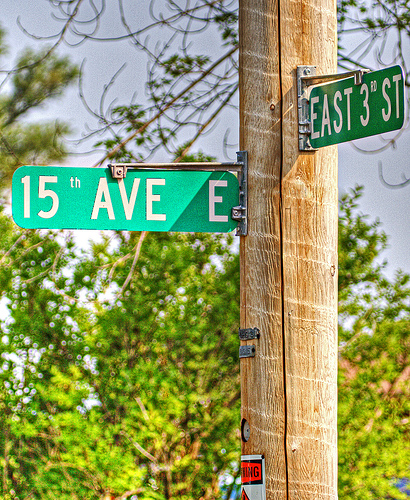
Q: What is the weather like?
A: It is clear.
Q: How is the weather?
A: It is clear.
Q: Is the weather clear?
A: Yes, it is clear.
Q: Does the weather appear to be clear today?
A: Yes, it is clear.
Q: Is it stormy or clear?
A: It is clear.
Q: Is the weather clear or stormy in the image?
A: It is clear.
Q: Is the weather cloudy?
A: No, it is clear.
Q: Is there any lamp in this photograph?
A: No, there are no lamps.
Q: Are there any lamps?
A: No, there are no lamps.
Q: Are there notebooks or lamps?
A: No, there are no lamps or notebooks.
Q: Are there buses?
A: No, there are no buses.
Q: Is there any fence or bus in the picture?
A: No, there are no buses or fences.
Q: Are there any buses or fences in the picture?
A: No, there are no buses or fences.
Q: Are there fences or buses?
A: No, there are no buses or fences.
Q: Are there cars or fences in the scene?
A: No, there are no fences or cars.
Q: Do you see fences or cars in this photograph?
A: No, there are no fences or cars.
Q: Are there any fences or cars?
A: No, there are no fences or cars.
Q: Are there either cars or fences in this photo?
A: No, there are no fences or cars.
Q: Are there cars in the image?
A: No, there are no cars.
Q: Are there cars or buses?
A: No, there are no cars or buses.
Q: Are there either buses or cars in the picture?
A: No, there are no cars or buses.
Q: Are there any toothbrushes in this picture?
A: No, there are no toothbrushes.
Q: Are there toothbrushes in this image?
A: No, there are no toothbrushes.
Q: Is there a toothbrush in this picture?
A: No, there are no toothbrushes.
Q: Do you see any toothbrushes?
A: No, there are no toothbrushes.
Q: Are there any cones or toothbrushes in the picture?
A: No, there are no toothbrushes or cones.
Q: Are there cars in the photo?
A: No, there are no cars.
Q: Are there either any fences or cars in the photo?
A: No, there are no cars or fences.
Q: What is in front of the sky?
A: The trees are in front of the sky.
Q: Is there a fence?
A: No, there are no fences.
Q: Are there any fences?
A: No, there are no fences.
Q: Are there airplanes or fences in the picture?
A: No, there are no fences or airplanes.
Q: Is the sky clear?
A: Yes, the sky is clear.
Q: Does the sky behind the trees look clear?
A: Yes, the sky is clear.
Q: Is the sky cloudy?
A: No, the sky is clear.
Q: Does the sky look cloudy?
A: No, the sky is clear.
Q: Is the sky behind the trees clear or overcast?
A: The sky is clear.